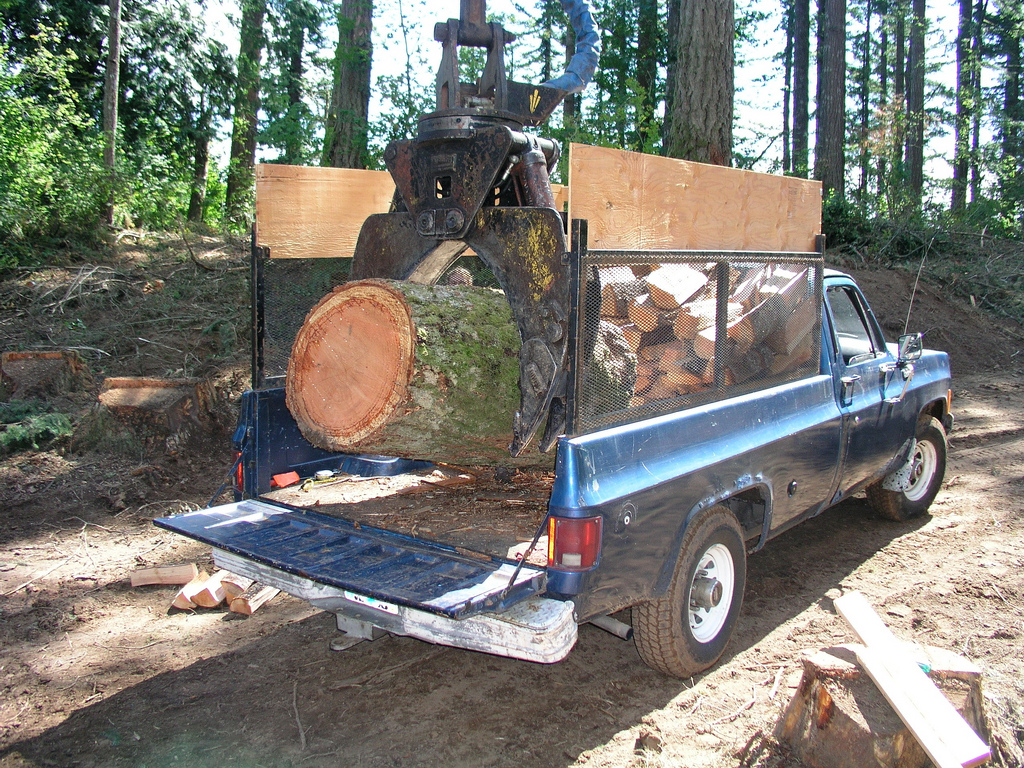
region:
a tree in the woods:
[67, 7, 135, 222]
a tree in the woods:
[212, 10, 277, 220]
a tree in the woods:
[256, 4, 314, 164]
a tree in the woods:
[326, 1, 381, 153]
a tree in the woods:
[585, 0, 634, 130]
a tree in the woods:
[620, 4, 666, 131]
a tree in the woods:
[650, 9, 724, 165]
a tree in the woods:
[811, 3, 851, 215]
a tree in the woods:
[898, 4, 928, 213]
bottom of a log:
[280, 283, 407, 446]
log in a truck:
[288, 278, 517, 459]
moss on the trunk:
[409, 296, 520, 424]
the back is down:
[149, 492, 541, 623]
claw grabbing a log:
[286, 3, 599, 469]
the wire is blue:
[539, 1, 598, 88]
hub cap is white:
[689, 545, 731, 641]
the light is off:
[545, 513, 596, 574]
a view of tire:
[631, 508, 818, 734]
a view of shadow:
[135, 626, 398, 759]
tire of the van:
[585, 467, 783, 682]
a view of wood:
[305, 195, 477, 470]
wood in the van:
[350, 271, 531, 557]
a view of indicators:
[553, 487, 637, 637]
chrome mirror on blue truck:
[883, 330, 932, 389]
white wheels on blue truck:
[655, 451, 786, 690]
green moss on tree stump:
[426, 290, 512, 426]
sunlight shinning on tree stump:
[87, 353, 228, 456]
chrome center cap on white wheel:
[677, 513, 741, 679]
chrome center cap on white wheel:
[902, 432, 944, 506]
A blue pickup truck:
[152, 137, 955, 681]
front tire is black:
[862, 412, 951, 523]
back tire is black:
[640, 501, 754, 683]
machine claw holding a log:
[283, 0, 597, 471]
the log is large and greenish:
[284, 271, 638, 467]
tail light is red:
[544, 514, 599, 568]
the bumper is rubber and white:
[211, 548, 578, 663]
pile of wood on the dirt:
[120, 549, 280, 620]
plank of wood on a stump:
[771, 593, 994, 767]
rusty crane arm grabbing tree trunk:
[275, 1, 582, 492]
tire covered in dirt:
[623, 485, 754, 686]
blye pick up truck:
[144, 140, 951, 682]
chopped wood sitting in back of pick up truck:
[574, 256, 827, 413]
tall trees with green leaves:
[0, 1, 1021, 296]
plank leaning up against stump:
[777, 582, 1019, 761]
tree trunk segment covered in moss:
[253, 253, 639, 475]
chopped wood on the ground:
[111, 548, 292, 624]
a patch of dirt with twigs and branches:
[0, 670, 101, 754]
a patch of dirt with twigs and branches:
[94, 669, 184, 762]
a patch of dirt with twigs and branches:
[174, 667, 280, 766]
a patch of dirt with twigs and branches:
[266, 672, 394, 765]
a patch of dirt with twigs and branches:
[550, 677, 637, 766]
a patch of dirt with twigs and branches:
[616, 682, 712, 763]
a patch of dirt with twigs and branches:
[942, 552, 1015, 628]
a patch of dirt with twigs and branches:
[0, 503, 112, 580]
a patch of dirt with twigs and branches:
[84, 458, 184, 528]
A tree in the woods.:
[819, 0, 861, 223]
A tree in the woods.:
[765, 17, 811, 185]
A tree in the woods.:
[825, 14, 896, 226]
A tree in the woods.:
[849, 30, 907, 231]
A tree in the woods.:
[938, 8, 984, 223]